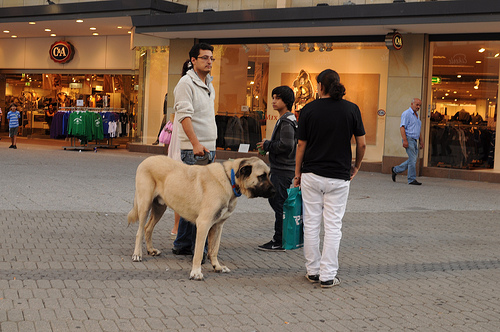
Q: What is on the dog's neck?
A: Collar.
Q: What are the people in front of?
A: Stores.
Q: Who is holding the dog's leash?
A: Man with glasses.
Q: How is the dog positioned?
A: Standing.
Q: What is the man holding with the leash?
A: Dog.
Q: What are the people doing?
A: Talking.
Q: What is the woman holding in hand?
A: Bag.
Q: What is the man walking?
A: Dog.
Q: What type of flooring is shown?
A: Brick.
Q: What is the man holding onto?
A: Dog.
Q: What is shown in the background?
A: Stores.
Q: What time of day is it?
A: Evening.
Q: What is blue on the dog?
A: Leash.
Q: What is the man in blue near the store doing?
A: Walking.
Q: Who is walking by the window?
A: An old man.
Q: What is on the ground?
A: Cement bricks.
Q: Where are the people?
A: In the mall.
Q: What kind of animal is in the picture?
A: A dog.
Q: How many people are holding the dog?
A: One.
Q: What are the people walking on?
A: Bricks.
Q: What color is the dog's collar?
A: Blue.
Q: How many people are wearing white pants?
A: One.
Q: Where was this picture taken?
A: At a mall.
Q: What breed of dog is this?
A: A mastiff.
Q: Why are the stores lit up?
A: They are open.